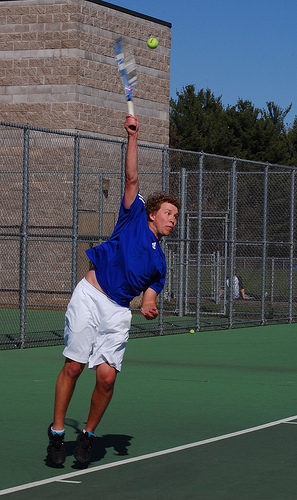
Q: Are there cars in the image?
A: No, there are no cars.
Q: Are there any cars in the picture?
A: No, there are no cars.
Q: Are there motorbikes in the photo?
A: No, there are no motorbikes.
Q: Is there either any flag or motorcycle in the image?
A: No, there are no motorcycles or flags.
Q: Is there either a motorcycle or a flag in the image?
A: No, there are no motorcycles or flags.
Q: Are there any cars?
A: No, there are no cars.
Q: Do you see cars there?
A: No, there are no cars.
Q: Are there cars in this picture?
A: No, there are no cars.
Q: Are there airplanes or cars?
A: No, there are no cars or airplanes.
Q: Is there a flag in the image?
A: No, there are no flags.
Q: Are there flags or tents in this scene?
A: No, there are no flags or tents.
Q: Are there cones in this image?
A: No, there are no cones.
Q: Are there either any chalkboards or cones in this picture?
A: No, there are no cones or chalkboards.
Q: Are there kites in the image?
A: No, there are no kites.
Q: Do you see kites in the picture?
A: No, there are no kites.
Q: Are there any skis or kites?
A: No, there are no kites or skis.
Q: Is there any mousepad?
A: No, there are no mouse pads.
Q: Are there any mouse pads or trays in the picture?
A: No, there are no mouse pads or trays.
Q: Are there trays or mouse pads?
A: No, there are no mouse pads or trays.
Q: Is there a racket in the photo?
A: Yes, there is a racket.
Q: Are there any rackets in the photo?
A: Yes, there is a racket.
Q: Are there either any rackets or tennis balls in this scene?
A: Yes, there is a racket.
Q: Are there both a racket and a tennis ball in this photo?
A: Yes, there are both a racket and a tennis ball.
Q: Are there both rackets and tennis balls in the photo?
A: Yes, there are both a racket and a tennis ball.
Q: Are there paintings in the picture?
A: No, there are no paintings.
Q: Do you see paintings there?
A: No, there are no paintings.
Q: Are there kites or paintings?
A: No, there are no paintings or kites.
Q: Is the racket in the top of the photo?
A: Yes, the racket is in the top of the image.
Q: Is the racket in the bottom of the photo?
A: No, the racket is in the top of the image.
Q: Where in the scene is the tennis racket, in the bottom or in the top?
A: The tennis racket is in the top of the image.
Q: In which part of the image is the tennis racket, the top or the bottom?
A: The tennis racket is in the top of the image.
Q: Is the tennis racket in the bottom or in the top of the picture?
A: The tennis racket is in the top of the image.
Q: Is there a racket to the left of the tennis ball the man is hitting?
A: Yes, there is a racket to the left of the tennis ball.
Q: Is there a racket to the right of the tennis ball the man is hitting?
A: No, the racket is to the left of the tennis ball.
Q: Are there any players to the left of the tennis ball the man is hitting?
A: No, there is a racket to the left of the tennis ball.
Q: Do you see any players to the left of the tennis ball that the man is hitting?
A: No, there is a racket to the left of the tennis ball.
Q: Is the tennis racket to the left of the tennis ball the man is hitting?
A: Yes, the tennis racket is to the left of the tennis ball.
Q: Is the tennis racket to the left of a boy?
A: No, the tennis racket is to the left of the tennis ball.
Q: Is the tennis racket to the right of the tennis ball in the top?
A: No, the tennis racket is to the left of the tennis ball.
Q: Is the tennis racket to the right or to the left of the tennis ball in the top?
A: The tennis racket is to the left of the tennis ball.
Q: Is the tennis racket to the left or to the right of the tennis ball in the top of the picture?
A: The tennis racket is to the left of the tennis ball.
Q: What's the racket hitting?
A: The tennis racket is hitting the tennis ball.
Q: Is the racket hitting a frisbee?
A: No, the racket is hitting a tennis ball.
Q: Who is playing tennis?
A: The man is playing tennis.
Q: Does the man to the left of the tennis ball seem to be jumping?
A: Yes, the man is jumping.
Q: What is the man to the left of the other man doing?
A: The man is jumping.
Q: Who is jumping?
A: The man is jumping.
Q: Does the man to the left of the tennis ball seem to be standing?
A: No, the man is jumping.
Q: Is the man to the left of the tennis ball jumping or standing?
A: The man is jumping.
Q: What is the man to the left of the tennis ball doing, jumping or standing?
A: The man is jumping.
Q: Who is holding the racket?
A: The man is holding the racket.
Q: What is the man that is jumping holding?
A: The man is holding the tennis racket.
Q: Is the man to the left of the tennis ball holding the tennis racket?
A: Yes, the man is holding the tennis racket.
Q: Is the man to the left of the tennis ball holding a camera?
A: No, the man is holding the tennis racket.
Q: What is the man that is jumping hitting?
A: The man is hitting the tennis ball.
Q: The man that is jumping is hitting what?
A: The man is hitting the tennis ball.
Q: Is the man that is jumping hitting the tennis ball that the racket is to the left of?
A: Yes, the man is hitting the tennis ball.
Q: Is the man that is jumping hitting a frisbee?
A: No, the man is hitting the tennis ball.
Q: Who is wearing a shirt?
A: The man is wearing a shirt.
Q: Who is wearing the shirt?
A: The man is wearing a shirt.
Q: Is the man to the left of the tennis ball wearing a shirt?
A: Yes, the man is wearing a shirt.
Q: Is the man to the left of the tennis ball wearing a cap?
A: No, the man is wearing a shirt.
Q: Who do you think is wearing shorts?
A: The man is wearing shorts.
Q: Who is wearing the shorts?
A: The man is wearing shorts.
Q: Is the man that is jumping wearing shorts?
A: Yes, the man is wearing shorts.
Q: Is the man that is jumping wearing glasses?
A: No, the man is wearing shorts.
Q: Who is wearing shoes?
A: The man is wearing shoes.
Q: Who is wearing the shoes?
A: The man is wearing shoes.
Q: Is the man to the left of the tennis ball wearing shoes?
A: Yes, the man is wearing shoes.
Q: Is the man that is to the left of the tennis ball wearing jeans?
A: No, the man is wearing shoes.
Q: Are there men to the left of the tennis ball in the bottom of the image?
A: Yes, there is a man to the left of the tennis ball.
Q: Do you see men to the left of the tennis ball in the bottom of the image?
A: Yes, there is a man to the left of the tennis ball.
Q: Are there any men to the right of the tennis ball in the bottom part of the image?
A: No, the man is to the left of the tennis ball.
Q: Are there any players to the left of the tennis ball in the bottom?
A: No, there is a man to the left of the tennis ball.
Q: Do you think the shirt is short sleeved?
A: Yes, the shirt is short sleeved.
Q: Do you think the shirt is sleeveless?
A: No, the shirt is short sleeved.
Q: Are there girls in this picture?
A: No, there are no girls.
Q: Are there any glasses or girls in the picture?
A: No, there are no girls or glasses.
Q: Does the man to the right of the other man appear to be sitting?
A: Yes, the man is sitting.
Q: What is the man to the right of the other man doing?
A: The man is sitting.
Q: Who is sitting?
A: The man is sitting.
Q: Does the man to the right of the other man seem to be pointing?
A: No, the man is sitting.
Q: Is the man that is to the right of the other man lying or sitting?
A: The man is sitting.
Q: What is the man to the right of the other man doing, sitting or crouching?
A: The man is sitting.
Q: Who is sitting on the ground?
A: The man is sitting on the ground.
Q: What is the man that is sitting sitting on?
A: The man is sitting on the ground.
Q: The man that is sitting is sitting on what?
A: The man is sitting on the ground.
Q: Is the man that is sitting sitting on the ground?
A: Yes, the man is sitting on the ground.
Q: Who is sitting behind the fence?
A: The man is sitting behind the fence.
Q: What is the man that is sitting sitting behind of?
A: The man is sitting behind the fence.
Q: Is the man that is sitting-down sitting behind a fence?
A: Yes, the man is sitting behind a fence.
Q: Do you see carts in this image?
A: No, there are no carts.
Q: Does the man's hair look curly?
A: Yes, the hair is curly.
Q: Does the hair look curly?
A: Yes, the hair is curly.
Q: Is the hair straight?
A: No, the hair is curly.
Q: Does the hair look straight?
A: No, the hair is curly.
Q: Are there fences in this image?
A: Yes, there is a fence.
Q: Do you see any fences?
A: Yes, there is a fence.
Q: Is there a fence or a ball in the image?
A: Yes, there is a fence.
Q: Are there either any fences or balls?
A: Yes, there is a fence.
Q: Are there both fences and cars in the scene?
A: No, there is a fence but no cars.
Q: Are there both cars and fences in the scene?
A: No, there is a fence but no cars.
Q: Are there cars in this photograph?
A: No, there are no cars.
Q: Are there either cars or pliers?
A: No, there are no cars or pliers.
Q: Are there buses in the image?
A: No, there are no buses.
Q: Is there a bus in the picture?
A: No, there are no buses.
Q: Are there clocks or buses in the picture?
A: No, there are no buses or clocks.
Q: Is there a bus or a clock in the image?
A: No, there are no buses or clocks.